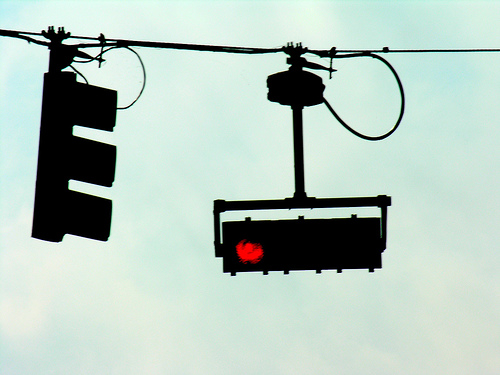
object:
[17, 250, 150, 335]
cloud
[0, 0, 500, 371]
sky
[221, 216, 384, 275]
traffic light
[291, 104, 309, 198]
pole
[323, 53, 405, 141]
lines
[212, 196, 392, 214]
base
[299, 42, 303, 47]
screw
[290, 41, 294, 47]
screw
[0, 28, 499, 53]
electrical line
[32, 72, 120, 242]
traffic light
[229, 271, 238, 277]
slot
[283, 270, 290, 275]
slot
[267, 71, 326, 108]
rotating piece